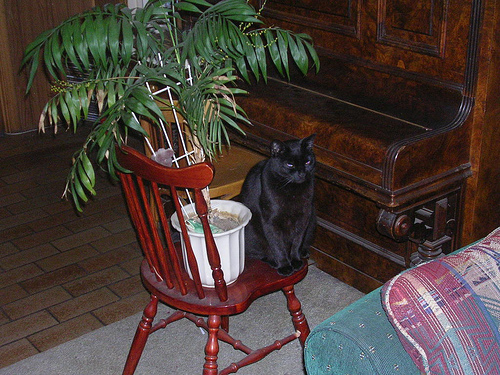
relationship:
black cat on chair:
[236, 127, 324, 284] [73, 121, 328, 373]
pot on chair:
[178, 181, 311, 285] [99, 81, 329, 371]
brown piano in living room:
[171, 2, 500, 295] [3, 3, 499, 373]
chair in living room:
[96, 111, 309, 373] [12, 44, 475, 373]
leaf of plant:
[95, 81, 104, 113] [16, 1, 324, 290]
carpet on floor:
[0, 265, 370, 373] [4, 221, 374, 368]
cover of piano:
[233, 75, 428, 199] [98, 1, 497, 291]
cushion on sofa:
[383, 228, 498, 372] [303, 222, 498, 373]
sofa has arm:
[303, 222, 498, 373] [302, 283, 424, 373]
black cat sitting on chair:
[239, 132, 318, 276] [111, 143, 312, 375]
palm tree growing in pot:
[15, 0, 320, 224] [168, 194, 254, 290]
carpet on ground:
[11, 265, 371, 370] [17, 147, 364, 369]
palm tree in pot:
[15, 0, 320, 224] [168, 194, 254, 290]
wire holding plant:
[129, 107, 161, 158] [110, 10, 212, 124]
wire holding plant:
[135, 60, 195, 205] [110, 10, 212, 124]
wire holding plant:
[156, 51, 194, 167] [110, 10, 212, 124]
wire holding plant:
[184, 57, 195, 89] [110, 10, 212, 124]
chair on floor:
[111, 143, 312, 375] [0, 124, 371, 374]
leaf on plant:
[94, 84, 104, 113] [16, 1, 324, 290]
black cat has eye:
[239, 132, 318, 276] [284, 157, 295, 168]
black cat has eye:
[239, 132, 318, 276] [304, 158, 312, 168]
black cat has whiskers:
[239, 132, 318, 276] [284, 171, 315, 182]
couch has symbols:
[302, 222, 499, 372] [411, 278, 453, 339]